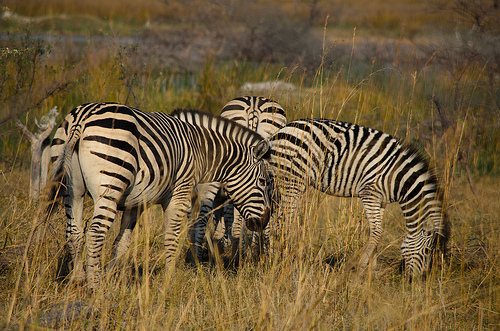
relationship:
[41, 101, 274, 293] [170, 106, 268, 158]
zebra has mane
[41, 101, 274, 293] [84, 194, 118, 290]
zebra has legs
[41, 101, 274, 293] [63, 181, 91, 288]
zebra has left rear leg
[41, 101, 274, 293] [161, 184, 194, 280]
zebra has right front leg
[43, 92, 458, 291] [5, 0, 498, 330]
zebras standing in grass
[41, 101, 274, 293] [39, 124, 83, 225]
zebra has tail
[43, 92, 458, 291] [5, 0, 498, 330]
zebras eating grass